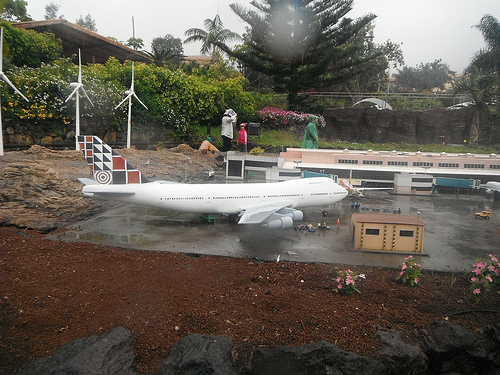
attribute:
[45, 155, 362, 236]
plane — white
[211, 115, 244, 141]
jacket — red, white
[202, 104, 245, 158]
man — dressed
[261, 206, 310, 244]
wind turbine — white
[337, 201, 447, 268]
shed — brown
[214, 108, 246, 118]
hat — white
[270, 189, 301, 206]
window — here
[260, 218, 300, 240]
engine — here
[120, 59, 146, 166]
wind mill — here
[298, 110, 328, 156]
person — here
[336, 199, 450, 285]
building — small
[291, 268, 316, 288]
rock — here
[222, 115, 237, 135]
coat — beige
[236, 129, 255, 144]
shirt — red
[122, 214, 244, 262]
asphalt — here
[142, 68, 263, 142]
bush — green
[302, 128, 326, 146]
suit — green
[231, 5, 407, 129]
tree — green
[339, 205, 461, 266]
house — brown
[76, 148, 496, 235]
airport — large, here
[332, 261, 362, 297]
flower — pink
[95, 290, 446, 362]
mulch — here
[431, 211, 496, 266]
puddle — here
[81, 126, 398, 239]
airplane — large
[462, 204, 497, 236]
car — small